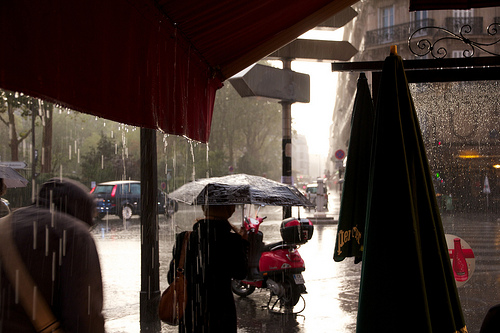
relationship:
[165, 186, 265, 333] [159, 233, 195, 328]
lady carrying purse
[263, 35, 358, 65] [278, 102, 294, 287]
sign on pole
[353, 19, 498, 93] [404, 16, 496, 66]
balcony above window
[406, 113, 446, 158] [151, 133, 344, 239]
ground holding umbrella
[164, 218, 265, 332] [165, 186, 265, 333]
coat on lady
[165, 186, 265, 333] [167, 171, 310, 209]
lady under umbrella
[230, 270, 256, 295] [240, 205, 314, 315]
wheel on motorbike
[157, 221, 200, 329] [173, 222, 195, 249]
purse on shoulder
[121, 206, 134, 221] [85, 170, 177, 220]
tire on car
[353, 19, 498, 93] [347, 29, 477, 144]
balcony on building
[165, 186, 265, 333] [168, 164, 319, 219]
lady carrying umbrella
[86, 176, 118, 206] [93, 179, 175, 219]
tail lights on car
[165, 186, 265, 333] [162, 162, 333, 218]
lady holding umbrella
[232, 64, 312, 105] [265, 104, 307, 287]
sign on pole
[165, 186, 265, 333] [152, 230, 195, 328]
lady carrying purse